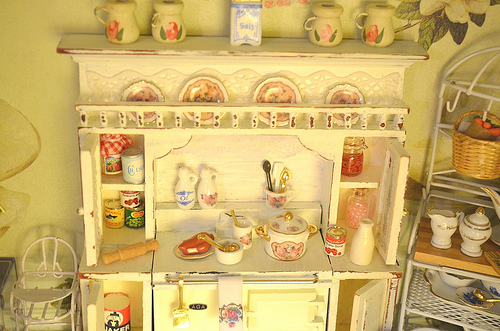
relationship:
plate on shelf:
[322, 71, 371, 130] [79, 113, 404, 136]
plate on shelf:
[250, 73, 301, 125] [79, 113, 404, 136]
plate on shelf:
[176, 77, 230, 126] [79, 113, 404, 136]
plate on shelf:
[124, 80, 164, 122] [79, 113, 404, 136]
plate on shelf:
[176, 77, 230, 126] [68, 98, 410, 136]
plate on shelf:
[250, 73, 301, 125] [72, 94, 414, 139]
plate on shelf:
[322, 71, 371, 130] [83, 102, 418, 137]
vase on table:
[346, 214, 381, 269] [38, 23, 420, 328]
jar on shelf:
[342, 138, 365, 174] [100, 172, 142, 187]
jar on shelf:
[464, 203, 491, 255] [337, 215, 378, 229]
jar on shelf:
[347, 186, 374, 228] [158, 197, 321, 210]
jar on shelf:
[171, 162, 196, 205] [416, 246, 493, 268]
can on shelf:
[125, 205, 147, 230] [91, 130, 151, 192]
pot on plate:
[252, 207, 320, 261] [252, 212, 326, 273]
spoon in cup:
[261, 158, 271, 193] [261, 186, 294, 208]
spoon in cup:
[274, 158, 281, 185] [261, 186, 294, 208]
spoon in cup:
[281, 168, 288, 191] [261, 186, 294, 208]